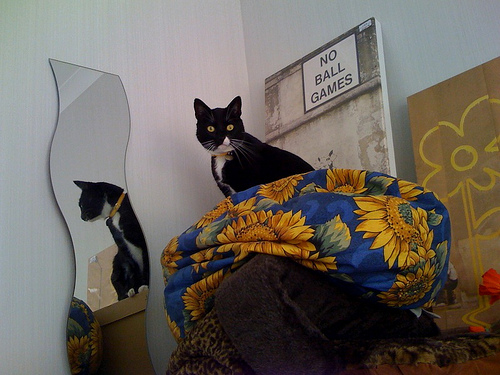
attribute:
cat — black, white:
[193, 96, 316, 198]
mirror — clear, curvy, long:
[48, 58, 158, 374]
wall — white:
[1, 1, 257, 372]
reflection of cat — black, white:
[72, 180, 150, 301]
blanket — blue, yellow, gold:
[161, 169, 450, 344]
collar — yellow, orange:
[213, 151, 234, 161]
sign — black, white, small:
[301, 32, 361, 116]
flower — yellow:
[419, 94, 500, 328]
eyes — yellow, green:
[207, 124, 234, 132]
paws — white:
[128, 284, 148, 297]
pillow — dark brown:
[215, 252, 442, 373]